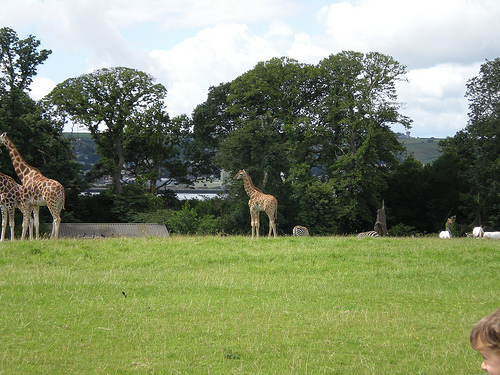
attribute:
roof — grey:
[56, 129, 219, 179]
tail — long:
[274, 196, 279, 224]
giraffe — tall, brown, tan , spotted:
[233, 168, 280, 237]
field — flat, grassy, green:
[1, 232, 498, 369]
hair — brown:
[468, 310, 498, 351]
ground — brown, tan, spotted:
[418, 201, 421, 218]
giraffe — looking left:
[218, 167, 300, 244]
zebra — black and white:
[291, 228, 319, 239]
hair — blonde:
[468, 310, 498, 358]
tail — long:
[273, 199, 280, 221]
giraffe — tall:
[199, 126, 366, 331]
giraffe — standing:
[235, 158, 301, 244]